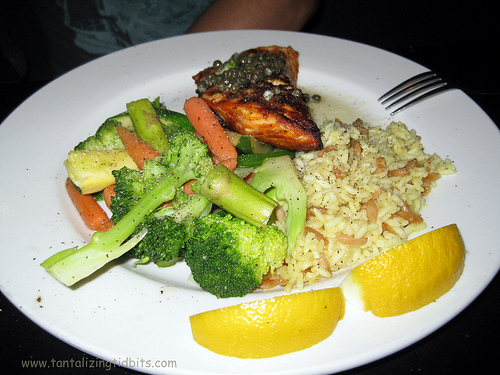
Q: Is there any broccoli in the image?
A: Yes, there is broccoli.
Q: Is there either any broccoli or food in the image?
A: Yes, there is broccoli.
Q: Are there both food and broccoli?
A: Yes, there are both broccoli and food.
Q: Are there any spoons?
A: No, there are no spoons.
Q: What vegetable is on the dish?
A: The vegetable is broccoli.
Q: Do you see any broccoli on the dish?
A: Yes, there is broccoli on the dish.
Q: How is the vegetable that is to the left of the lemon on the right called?
A: The vegetable is broccoli.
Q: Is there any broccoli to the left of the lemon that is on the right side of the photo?
A: Yes, there is broccoli to the left of the lemon.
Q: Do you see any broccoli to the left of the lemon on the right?
A: Yes, there is broccoli to the left of the lemon.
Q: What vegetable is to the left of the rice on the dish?
A: The vegetable is broccoli.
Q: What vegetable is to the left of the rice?
A: The vegetable is broccoli.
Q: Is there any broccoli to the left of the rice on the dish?
A: Yes, there is broccoli to the left of the rice.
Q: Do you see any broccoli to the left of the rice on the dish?
A: Yes, there is broccoli to the left of the rice.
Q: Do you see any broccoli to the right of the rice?
A: No, the broccoli is to the left of the rice.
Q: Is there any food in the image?
A: Yes, there is food.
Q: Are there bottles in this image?
A: No, there are no bottles.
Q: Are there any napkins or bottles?
A: No, there are no bottles or napkins.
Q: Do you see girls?
A: No, there are no girls.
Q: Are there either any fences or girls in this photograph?
A: No, there are no girls or fences.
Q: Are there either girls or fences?
A: No, there are no girls or fences.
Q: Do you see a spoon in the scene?
A: No, there are no spoons.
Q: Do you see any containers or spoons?
A: No, there are no spoons or containers.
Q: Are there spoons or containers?
A: No, there are no spoons or containers.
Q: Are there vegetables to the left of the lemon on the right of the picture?
A: Yes, there is a vegetable to the left of the lemon.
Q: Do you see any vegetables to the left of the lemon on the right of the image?
A: Yes, there is a vegetable to the left of the lemon.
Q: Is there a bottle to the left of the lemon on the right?
A: No, there is a vegetable to the left of the lemon.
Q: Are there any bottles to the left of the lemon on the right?
A: No, there is a vegetable to the left of the lemon.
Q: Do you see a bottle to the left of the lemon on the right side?
A: No, there is a vegetable to the left of the lemon.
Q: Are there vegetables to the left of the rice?
A: Yes, there is a vegetable to the left of the rice.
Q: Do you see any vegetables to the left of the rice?
A: Yes, there is a vegetable to the left of the rice.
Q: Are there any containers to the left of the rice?
A: No, there is a vegetable to the left of the rice.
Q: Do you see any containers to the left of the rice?
A: No, there is a vegetable to the left of the rice.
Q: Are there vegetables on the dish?
A: Yes, there is a vegetable on the dish.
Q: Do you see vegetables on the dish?
A: Yes, there is a vegetable on the dish.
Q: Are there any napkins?
A: No, there are no napkins.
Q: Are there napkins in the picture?
A: No, there are no napkins.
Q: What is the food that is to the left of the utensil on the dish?
A: The food is salmon.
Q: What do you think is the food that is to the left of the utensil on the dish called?
A: The food is salmon.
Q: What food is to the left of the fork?
A: The food is salmon.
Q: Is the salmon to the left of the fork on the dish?
A: Yes, the salmon is to the left of the fork.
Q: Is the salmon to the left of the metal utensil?
A: Yes, the salmon is to the left of the fork.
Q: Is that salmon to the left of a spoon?
A: No, the salmon is to the left of the fork.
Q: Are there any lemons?
A: Yes, there is a lemon.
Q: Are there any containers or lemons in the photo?
A: Yes, there is a lemon.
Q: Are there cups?
A: No, there are no cups.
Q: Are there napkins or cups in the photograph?
A: No, there are no cups or napkins.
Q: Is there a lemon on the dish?
A: Yes, there is a lemon on the dish.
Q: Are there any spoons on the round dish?
A: No, there is a lemon on the dish.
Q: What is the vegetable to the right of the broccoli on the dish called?
A: The vegetable is a lemon.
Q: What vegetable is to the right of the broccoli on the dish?
A: The vegetable is a lemon.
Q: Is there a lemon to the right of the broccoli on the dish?
A: Yes, there is a lemon to the right of the broccoli.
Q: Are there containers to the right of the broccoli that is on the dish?
A: No, there is a lemon to the right of the broccoli.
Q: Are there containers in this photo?
A: No, there are no containers.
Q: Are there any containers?
A: No, there are no containers.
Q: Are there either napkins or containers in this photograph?
A: No, there are no containers or napkins.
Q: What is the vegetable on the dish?
A: The vegetable is a lemon.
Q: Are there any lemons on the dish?
A: Yes, there is a lemon on the dish.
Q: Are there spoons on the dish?
A: No, there is a lemon on the dish.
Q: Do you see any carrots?
A: Yes, there are carrots.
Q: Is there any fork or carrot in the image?
A: Yes, there are carrots.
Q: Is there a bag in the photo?
A: No, there are no bags.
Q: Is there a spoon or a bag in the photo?
A: No, there are no bags or spoons.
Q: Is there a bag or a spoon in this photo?
A: No, there are no bags or spoons.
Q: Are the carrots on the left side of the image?
A: Yes, the carrots are on the left of the image.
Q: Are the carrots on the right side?
A: No, the carrots are on the left of the image.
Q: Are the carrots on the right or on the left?
A: The carrots are on the left of the image.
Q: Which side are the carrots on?
A: The carrots are on the left of the image.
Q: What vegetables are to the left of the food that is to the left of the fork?
A: The vegetables are carrots.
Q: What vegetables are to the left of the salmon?
A: The vegetables are carrots.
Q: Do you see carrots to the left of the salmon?
A: Yes, there are carrots to the left of the salmon.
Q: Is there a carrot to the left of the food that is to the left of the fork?
A: Yes, there are carrots to the left of the salmon.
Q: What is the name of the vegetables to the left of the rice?
A: The vegetables are carrots.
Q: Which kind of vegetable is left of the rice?
A: The vegetables are carrots.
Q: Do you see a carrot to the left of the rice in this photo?
A: Yes, there are carrots to the left of the rice.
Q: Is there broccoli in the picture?
A: Yes, there is broccoli.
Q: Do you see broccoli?
A: Yes, there is broccoli.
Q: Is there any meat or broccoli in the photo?
A: Yes, there is broccoli.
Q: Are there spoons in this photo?
A: No, there are no spoons.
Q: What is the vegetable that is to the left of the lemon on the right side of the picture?
A: The vegetable is broccoli.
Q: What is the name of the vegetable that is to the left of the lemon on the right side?
A: The vegetable is broccoli.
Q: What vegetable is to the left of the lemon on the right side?
A: The vegetable is broccoli.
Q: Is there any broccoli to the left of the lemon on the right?
A: Yes, there is broccoli to the left of the lemon.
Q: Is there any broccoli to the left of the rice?
A: Yes, there is broccoli to the left of the rice.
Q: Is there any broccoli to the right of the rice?
A: No, the broccoli is to the left of the rice.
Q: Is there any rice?
A: Yes, there is rice.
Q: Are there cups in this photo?
A: No, there are no cups.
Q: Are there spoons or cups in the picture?
A: No, there are no cups or spoons.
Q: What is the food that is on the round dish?
A: The food is rice.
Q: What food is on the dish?
A: The food is rice.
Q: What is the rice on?
A: The rice is on the dish.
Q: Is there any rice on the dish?
A: Yes, there is rice on the dish.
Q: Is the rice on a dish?
A: Yes, the rice is on a dish.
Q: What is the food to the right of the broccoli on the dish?
A: The food is rice.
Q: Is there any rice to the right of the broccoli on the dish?
A: Yes, there is rice to the right of the broccoli.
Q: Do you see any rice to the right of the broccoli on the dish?
A: Yes, there is rice to the right of the broccoli.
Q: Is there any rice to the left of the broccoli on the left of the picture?
A: No, the rice is to the right of the broccoli.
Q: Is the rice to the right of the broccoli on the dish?
A: Yes, the rice is to the right of the broccoli.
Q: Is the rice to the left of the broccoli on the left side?
A: No, the rice is to the right of the broccoli.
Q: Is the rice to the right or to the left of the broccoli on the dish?
A: The rice is to the right of the broccoli.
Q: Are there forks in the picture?
A: Yes, there is a fork.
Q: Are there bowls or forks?
A: Yes, there is a fork.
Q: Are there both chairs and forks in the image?
A: No, there is a fork but no chairs.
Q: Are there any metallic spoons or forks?
A: Yes, there is a metal fork.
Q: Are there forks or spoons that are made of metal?
A: Yes, the fork is made of metal.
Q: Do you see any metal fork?
A: Yes, there is a fork that is made of metal.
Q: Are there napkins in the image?
A: No, there are no napkins.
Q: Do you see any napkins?
A: No, there are no napkins.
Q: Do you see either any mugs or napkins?
A: No, there are no napkins or mugs.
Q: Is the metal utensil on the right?
A: Yes, the fork is on the right of the image.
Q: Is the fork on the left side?
A: No, the fork is on the right of the image.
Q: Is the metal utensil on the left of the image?
A: No, the fork is on the right of the image.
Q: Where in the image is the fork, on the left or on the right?
A: The fork is on the right of the image.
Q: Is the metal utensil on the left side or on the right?
A: The fork is on the right of the image.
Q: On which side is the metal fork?
A: The fork is on the right of the image.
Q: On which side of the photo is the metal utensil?
A: The fork is on the right of the image.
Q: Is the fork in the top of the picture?
A: Yes, the fork is in the top of the image.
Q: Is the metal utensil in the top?
A: Yes, the fork is in the top of the image.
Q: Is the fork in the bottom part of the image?
A: No, the fork is in the top of the image.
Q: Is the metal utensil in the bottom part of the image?
A: No, the fork is in the top of the image.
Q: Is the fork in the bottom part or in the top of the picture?
A: The fork is in the top of the image.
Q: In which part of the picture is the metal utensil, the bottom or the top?
A: The fork is in the top of the image.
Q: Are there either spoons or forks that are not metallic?
A: No, there is a fork but it is metallic.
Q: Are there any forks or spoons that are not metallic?
A: No, there is a fork but it is metallic.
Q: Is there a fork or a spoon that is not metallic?
A: No, there is a fork but it is metallic.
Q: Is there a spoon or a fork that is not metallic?
A: No, there is a fork but it is metallic.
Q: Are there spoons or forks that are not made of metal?
A: No, there is a fork but it is made of metal.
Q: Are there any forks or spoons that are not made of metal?
A: No, there is a fork but it is made of metal.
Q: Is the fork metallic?
A: Yes, the fork is metallic.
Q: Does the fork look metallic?
A: Yes, the fork is metallic.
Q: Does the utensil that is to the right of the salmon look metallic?
A: Yes, the fork is metallic.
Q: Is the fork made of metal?
A: Yes, the fork is made of metal.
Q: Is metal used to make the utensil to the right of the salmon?
A: Yes, the fork is made of metal.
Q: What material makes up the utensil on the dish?
A: The fork is made of metal.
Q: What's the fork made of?
A: The fork is made of metal.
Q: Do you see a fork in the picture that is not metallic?
A: No, there is a fork but it is metallic.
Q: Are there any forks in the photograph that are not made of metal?
A: No, there is a fork but it is made of metal.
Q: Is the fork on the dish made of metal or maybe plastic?
A: The fork is made of metal.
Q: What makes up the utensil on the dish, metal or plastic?
A: The fork is made of metal.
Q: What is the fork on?
A: The fork is on the dish.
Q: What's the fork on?
A: The fork is on the dish.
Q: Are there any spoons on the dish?
A: No, there is a fork on the dish.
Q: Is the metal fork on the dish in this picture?
A: Yes, the fork is on the dish.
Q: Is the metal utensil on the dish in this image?
A: Yes, the fork is on the dish.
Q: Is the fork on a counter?
A: No, the fork is on the dish.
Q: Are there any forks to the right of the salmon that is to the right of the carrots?
A: Yes, there is a fork to the right of the salmon.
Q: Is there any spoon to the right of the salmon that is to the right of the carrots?
A: No, there is a fork to the right of the salmon.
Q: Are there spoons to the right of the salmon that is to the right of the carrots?
A: No, there is a fork to the right of the salmon.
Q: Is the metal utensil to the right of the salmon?
A: Yes, the fork is to the right of the salmon.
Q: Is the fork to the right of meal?
A: No, the fork is to the right of the salmon.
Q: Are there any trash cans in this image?
A: No, there are no trash cans.